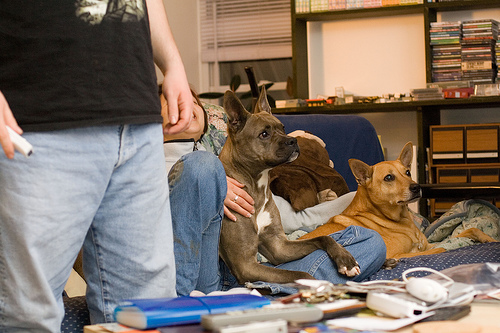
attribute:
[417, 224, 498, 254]
legs — long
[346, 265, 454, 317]
wii remote — white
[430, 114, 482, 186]
wooden boxes — brown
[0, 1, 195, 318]
man — standing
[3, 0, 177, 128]
t-shirt — black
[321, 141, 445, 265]
dog — tan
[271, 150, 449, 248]
dog — tan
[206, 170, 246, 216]
hand — person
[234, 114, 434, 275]
dog — light brown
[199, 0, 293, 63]
blinds — white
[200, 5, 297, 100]
window — pictured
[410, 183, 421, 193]
nose — black, small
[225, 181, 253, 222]
hand — woman's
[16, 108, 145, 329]
jeans — blue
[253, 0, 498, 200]
desk — large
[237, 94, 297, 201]
dog — brown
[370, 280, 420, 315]
remote — wii, white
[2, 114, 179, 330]
blue jeans — light-colored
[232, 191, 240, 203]
ring — silver